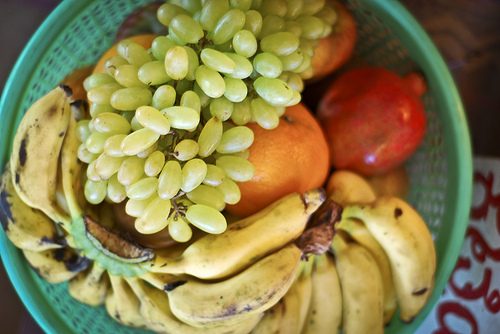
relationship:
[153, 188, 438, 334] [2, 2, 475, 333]
bananas in bowl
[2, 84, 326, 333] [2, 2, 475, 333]
bananas in bowl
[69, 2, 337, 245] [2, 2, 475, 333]
grapes in bowl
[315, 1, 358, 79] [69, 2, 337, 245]
orange under grapes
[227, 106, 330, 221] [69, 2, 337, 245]
orange under grapes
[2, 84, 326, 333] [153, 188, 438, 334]
bananas on top of bananas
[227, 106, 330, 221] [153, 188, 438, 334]
orange beside bananas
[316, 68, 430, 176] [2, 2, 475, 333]
pomegranate in bowl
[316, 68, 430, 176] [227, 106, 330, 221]
pomegranate beside orange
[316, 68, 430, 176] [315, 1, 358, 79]
pomegranate beside orange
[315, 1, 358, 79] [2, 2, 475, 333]
orange in bowl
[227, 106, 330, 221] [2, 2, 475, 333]
orange in bowl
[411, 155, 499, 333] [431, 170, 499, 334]
paper has lettering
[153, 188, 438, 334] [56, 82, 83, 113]
bananas have black tips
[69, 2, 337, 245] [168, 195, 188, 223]
grapes have stem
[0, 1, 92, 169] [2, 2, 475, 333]
rim of bowl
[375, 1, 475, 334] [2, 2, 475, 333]
rim of bowl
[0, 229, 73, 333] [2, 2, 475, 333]
rim of bowl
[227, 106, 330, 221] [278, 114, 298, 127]
orange has stem